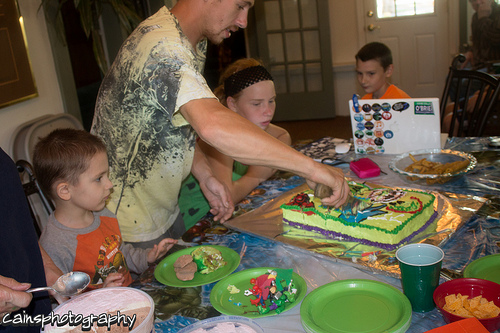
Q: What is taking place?
A: A party.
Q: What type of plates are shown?
A: Green.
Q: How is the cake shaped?
A: Rectangularly.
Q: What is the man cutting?
A: Cake.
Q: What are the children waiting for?
A: Cake.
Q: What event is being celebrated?
A: Birthday party.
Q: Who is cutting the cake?
A: A man.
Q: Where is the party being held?
A: Inside a house.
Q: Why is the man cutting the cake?
A: To serve it to the kids.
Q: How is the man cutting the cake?
A: With a knife.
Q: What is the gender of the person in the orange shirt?
A: Male.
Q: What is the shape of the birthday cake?
A: Rectangular.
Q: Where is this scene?
A: A dining room.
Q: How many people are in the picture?
A: 4.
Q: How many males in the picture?
A: 3.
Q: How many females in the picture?
A: 1.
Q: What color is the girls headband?
A: Black.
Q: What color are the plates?
A: Green.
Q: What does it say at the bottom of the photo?
A: Cainsphotography.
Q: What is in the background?
A: A door.